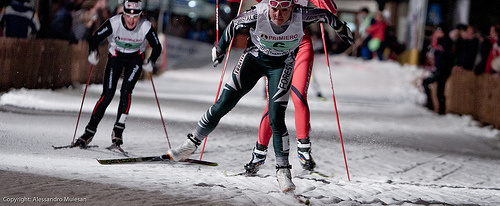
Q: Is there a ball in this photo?
A: No, there are no balls.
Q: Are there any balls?
A: No, there are no balls.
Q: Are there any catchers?
A: No, there are no catchers.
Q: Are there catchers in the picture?
A: No, there are no catchers.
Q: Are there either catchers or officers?
A: No, there are no catchers or officers.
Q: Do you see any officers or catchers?
A: No, there are no catchers or officers.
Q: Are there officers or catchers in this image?
A: No, there are no catchers or officers.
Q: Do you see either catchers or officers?
A: No, there are no catchers or officers.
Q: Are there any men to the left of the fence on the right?
A: Yes, there is a man to the left of the fence.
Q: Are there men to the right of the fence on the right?
A: No, the man is to the left of the fence.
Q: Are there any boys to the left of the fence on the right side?
A: No, there is a man to the left of the fence.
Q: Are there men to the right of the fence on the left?
A: Yes, there is a man to the right of the fence.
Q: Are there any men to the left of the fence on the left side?
A: No, the man is to the right of the fence.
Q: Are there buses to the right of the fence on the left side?
A: No, there is a man to the right of the fence.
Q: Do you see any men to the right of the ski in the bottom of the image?
A: Yes, there is a man to the right of the ski.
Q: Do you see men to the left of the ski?
A: No, the man is to the right of the ski.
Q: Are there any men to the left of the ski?
A: No, the man is to the right of the ski.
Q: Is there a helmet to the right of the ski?
A: No, there is a man to the right of the ski.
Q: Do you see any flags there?
A: Yes, there is a flag.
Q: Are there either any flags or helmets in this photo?
A: Yes, there is a flag.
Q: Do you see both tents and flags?
A: No, there is a flag but no tents.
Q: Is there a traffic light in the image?
A: No, there are no traffic lights.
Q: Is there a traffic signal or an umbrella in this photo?
A: No, there are no traffic lights or umbrellas.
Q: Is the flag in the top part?
A: Yes, the flag is in the top of the image.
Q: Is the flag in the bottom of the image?
A: No, the flag is in the top of the image.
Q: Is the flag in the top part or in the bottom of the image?
A: The flag is in the top of the image.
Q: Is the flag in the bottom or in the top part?
A: The flag is in the top of the image.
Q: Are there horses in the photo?
A: No, there are no horses.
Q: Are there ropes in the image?
A: No, there are no ropes.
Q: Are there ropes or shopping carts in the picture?
A: No, there are no ropes or shopping carts.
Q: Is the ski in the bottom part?
A: Yes, the ski is in the bottom of the image.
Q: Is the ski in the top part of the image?
A: No, the ski is in the bottom of the image.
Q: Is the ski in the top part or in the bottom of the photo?
A: The ski is in the bottom of the image.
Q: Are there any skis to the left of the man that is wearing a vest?
A: Yes, there is a ski to the left of the man.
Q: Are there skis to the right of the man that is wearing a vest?
A: No, the ski is to the left of the man.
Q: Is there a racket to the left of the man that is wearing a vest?
A: No, there is a ski to the left of the man.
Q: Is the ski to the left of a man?
A: Yes, the ski is to the left of a man.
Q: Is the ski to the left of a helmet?
A: No, the ski is to the left of a man.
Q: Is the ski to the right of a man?
A: No, the ski is to the left of a man.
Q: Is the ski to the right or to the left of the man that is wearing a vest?
A: The ski is to the left of the man.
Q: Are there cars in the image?
A: No, there are no cars.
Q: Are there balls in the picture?
A: No, there are no balls.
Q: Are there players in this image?
A: No, there are no players.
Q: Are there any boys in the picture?
A: No, there are no boys.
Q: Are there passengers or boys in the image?
A: No, there are no boys or passengers.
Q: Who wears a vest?
A: The man wears a vest.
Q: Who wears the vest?
A: The man wears a vest.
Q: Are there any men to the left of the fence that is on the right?
A: Yes, there is a man to the left of the fence.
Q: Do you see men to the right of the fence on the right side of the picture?
A: No, the man is to the left of the fence.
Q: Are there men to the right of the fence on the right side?
A: No, the man is to the left of the fence.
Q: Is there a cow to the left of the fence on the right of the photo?
A: No, there is a man to the left of the fence.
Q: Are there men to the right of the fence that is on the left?
A: Yes, there is a man to the right of the fence.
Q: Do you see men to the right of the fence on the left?
A: Yes, there is a man to the right of the fence.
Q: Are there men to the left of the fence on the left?
A: No, the man is to the right of the fence.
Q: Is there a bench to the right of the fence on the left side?
A: No, there is a man to the right of the fence.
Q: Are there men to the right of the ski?
A: Yes, there is a man to the right of the ski.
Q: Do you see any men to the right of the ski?
A: Yes, there is a man to the right of the ski.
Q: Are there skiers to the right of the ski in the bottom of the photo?
A: No, there is a man to the right of the ski.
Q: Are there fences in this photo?
A: Yes, there is a fence.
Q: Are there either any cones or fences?
A: Yes, there is a fence.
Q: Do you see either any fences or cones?
A: Yes, there is a fence.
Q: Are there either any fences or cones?
A: Yes, there is a fence.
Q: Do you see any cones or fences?
A: Yes, there is a fence.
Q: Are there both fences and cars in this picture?
A: No, there is a fence but no cars.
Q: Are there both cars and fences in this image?
A: No, there is a fence but no cars.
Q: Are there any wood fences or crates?
A: Yes, there is a wood fence.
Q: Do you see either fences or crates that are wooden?
A: Yes, the fence is wooden.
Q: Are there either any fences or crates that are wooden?
A: Yes, the fence is wooden.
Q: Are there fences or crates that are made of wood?
A: Yes, the fence is made of wood.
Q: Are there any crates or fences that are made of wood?
A: Yes, the fence is made of wood.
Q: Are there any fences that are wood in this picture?
A: Yes, there is a wood fence.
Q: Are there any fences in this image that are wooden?
A: Yes, there is a fence that is wooden.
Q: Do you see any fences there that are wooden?
A: Yes, there is a fence that is wooden.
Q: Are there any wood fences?
A: Yes, there is a fence that is made of wood.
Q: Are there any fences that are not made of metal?
A: Yes, there is a fence that is made of wood.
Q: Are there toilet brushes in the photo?
A: No, there are no toilet brushes.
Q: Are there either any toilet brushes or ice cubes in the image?
A: No, there are no toilet brushes or ice cubes.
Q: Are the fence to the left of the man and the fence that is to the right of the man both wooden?
A: Yes, both the fence and the fence are wooden.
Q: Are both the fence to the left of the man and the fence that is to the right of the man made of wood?
A: Yes, both the fence and the fence are made of wood.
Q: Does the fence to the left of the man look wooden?
A: Yes, the fence is wooden.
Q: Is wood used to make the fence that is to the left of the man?
A: Yes, the fence is made of wood.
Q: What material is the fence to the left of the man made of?
A: The fence is made of wood.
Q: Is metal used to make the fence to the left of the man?
A: No, the fence is made of wood.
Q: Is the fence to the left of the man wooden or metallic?
A: The fence is wooden.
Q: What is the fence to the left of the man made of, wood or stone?
A: The fence is made of wood.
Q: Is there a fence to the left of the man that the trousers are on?
A: Yes, there is a fence to the left of the man.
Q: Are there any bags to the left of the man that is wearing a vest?
A: No, there is a fence to the left of the man.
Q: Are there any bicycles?
A: No, there are no bicycles.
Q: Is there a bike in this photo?
A: No, there are no bikes.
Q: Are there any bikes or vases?
A: No, there are no bikes or vases.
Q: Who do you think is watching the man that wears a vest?
A: The crowd is watching the man.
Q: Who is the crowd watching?
A: The crowd is watching the man.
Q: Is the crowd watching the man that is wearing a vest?
A: Yes, the crowd is watching the man.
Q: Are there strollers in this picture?
A: No, there are no strollers.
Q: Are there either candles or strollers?
A: No, there are no strollers or candles.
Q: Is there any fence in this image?
A: Yes, there is a fence.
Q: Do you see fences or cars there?
A: Yes, there is a fence.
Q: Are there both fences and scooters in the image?
A: No, there is a fence but no scooters.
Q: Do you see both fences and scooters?
A: No, there is a fence but no scooters.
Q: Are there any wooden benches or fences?
A: Yes, there is a wood fence.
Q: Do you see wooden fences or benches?
A: Yes, there is a wood fence.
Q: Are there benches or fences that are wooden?
A: Yes, the fence is wooden.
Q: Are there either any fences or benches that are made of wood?
A: Yes, the fence is made of wood.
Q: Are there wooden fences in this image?
A: Yes, there is a wood fence.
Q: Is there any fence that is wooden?
A: Yes, there is a fence that is wooden.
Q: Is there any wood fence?
A: Yes, there is a fence that is made of wood.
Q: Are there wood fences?
A: Yes, there is a fence that is made of wood.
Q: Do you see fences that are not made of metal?
A: Yes, there is a fence that is made of wood.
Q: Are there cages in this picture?
A: No, there are no cages.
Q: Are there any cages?
A: No, there are no cages.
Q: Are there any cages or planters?
A: No, there are no cages or planters.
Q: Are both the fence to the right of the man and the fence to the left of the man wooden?
A: Yes, both the fence and the fence are wooden.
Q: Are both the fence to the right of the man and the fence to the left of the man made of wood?
A: Yes, both the fence and the fence are made of wood.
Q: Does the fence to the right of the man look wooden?
A: Yes, the fence is wooden.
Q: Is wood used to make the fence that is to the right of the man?
A: Yes, the fence is made of wood.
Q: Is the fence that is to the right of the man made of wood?
A: Yes, the fence is made of wood.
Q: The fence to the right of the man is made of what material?
A: The fence is made of wood.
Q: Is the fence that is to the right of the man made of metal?
A: No, the fence is made of wood.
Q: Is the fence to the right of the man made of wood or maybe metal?
A: The fence is made of wood.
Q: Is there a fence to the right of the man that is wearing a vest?
A: Yes, there is a fence to the right of the man.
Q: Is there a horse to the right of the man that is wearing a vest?
A: No, there is a fence to the right of the man.